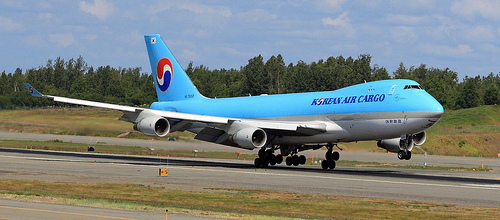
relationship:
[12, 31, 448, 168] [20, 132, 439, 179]
airplane on runway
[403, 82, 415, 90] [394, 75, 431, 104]
window on cockpit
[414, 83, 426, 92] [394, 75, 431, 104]
window on cockpit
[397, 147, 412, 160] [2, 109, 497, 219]
wheel off ground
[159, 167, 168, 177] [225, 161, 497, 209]
sign on runway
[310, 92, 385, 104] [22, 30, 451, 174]
lettering on plane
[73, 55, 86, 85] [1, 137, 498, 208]
tree growing by runway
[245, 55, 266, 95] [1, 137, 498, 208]
tree growing by runway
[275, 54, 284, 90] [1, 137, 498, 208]
tree growing by runway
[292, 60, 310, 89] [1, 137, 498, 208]
tree growing by runway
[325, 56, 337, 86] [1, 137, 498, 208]
tree growing by runway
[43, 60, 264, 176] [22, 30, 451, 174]
wing of plane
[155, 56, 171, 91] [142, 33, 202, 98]
airline logo on tail fin